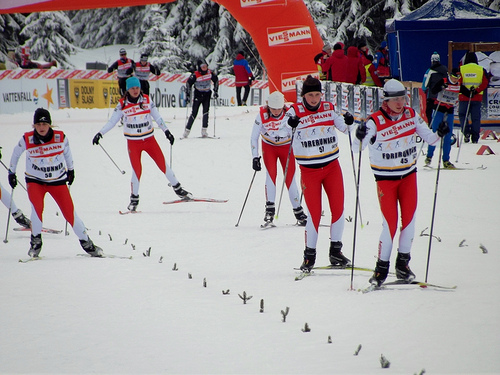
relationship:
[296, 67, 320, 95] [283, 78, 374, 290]
beanie on person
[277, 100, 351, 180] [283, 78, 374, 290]
shirt on person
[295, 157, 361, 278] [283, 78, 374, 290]
pants on person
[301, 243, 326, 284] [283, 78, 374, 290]
shoe on person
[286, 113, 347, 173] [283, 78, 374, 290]
vest on person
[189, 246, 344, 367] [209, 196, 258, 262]
divider in snow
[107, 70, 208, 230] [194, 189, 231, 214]
competitor wearing ski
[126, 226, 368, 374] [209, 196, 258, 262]
line in snow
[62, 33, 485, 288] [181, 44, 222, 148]
people behind skier